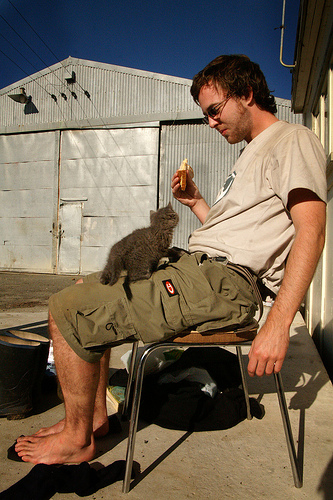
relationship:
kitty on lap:
[104, 216, 184, 278] [79, 263, 245, 352]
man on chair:
[46, 54, 307, 486] [140, 337, 301, 466]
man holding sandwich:
[46, 54, 307, 486] [178, 160, 194, 192]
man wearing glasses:
[46, 54, 307, 486] [197, 98, 232, 122]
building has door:
[1, 50, 273, 281] [2, 129, 164, 278]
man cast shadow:
[46, 54, 307, 486] [26, 460, 78, 500]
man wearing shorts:
[46, 54, 307, 486] [37, 237, 262, 339]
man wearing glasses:
[46, 54, 307, 486] [201, 92, 235, 126]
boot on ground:
[3, 314, 49, 418] [156, 440, 277, 500]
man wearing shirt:
[46, 54, 307, 486] [225, 116, 291, 287]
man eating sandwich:
[46, 54, 307, 486] [178, 160, 194, 192]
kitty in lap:
[104, 216, 184, 278] [79, 263, 245, 352]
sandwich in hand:
[178, 160, 194, 192] [164, 170, 198, 206]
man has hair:
[46, 54, 307, 486] [188, 46, 277, 112]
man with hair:
[46, 54, 307, 486] [188, 46, 277, 112]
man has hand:
[46, 54, 307, 486] [164, 170, 198, 206]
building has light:
[1, 50, 273, 281] [6, 79, 35, 115]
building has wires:
[1, 50, 273, 281] [4, 3, 88, 110]